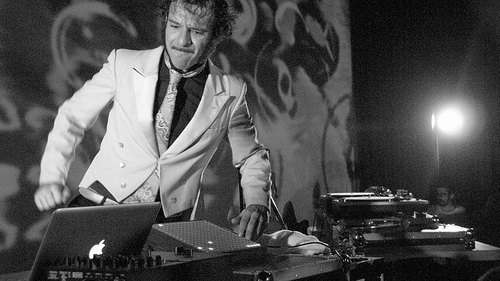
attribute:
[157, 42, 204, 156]
tie — long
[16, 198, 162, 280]
laptop — apple, silver, open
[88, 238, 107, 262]
logo — white, apple, silver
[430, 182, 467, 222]
person — sitting, man sitting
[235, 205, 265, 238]
hand — white , male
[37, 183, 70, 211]
hand — fist , white, male, close 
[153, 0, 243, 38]
hair — dark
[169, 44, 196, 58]
moustache — dark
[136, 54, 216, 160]
shirt — black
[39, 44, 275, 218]
jacket — white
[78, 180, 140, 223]
belt — gray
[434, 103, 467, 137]
light — bright, round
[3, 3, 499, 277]
picture — black, white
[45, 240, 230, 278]
equipment — mixing equipment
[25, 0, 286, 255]
man — not black